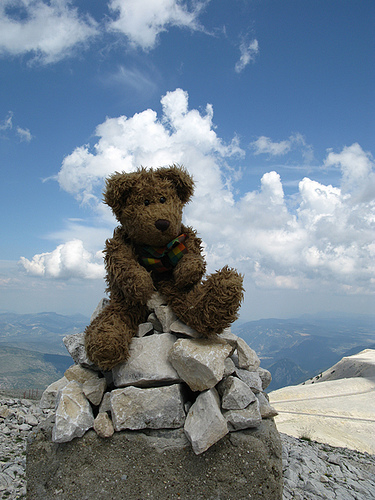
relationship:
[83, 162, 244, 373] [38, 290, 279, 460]
teddy bear sitting atop rocks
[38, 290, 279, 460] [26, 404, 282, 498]
rocks on top of base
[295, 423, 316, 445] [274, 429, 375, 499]
grass at edge of rocks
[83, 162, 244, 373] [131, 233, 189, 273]
teddy bear wearing ribbon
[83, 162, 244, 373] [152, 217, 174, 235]
teddy bear has nose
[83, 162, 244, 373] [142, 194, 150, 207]
teddy bear has eye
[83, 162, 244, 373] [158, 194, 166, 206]
teddy bear has eye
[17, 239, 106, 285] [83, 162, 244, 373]
clouds behind teddy bear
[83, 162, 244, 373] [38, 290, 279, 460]
teddy bear sitting on top of rocks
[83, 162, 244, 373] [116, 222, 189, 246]
teddy bear has neck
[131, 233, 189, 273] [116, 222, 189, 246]
ribbon around neck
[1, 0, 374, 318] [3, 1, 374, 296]
sky filled with clouds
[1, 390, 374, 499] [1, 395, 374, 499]
ground covered with rocks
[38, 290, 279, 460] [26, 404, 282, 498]
rocks on a base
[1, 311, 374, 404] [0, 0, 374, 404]
mountains in background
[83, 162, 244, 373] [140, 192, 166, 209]
teddy bear has close eyes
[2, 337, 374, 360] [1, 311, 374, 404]
road on top of mountains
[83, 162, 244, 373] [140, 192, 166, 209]
teddy bear has eyes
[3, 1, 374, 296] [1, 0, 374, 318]
clouds in sky